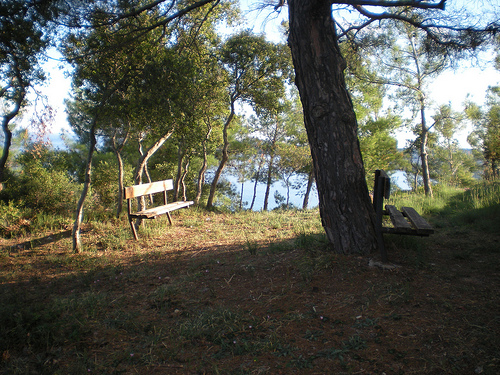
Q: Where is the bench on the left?
A: On the dirt.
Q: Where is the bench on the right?
A: On the tree.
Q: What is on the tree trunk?
A: Bark.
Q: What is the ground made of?
A: Grass and dirt.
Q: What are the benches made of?
A: Wood.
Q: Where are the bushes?
A: Behind the bench on the left.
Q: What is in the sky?
A: Clouds.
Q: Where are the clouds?
A: In the sky.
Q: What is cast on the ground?
A: Shadows.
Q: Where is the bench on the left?
A: On the ground.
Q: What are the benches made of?
A: Wood.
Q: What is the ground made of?
A: Grass and dirt.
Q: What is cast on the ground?
A: Shadows.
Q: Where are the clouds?
A: In the sky.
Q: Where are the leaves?
A: On the trees.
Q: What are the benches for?
A: Sitting.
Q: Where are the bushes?
A: Behind the left bench.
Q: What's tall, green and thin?
A: Tree trunk.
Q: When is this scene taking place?
A: Daytime.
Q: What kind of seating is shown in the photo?
A: Bench.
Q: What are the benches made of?
A: Wood.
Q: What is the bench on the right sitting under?
A: Tree.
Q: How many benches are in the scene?
A: Two.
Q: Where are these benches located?
A: Forest.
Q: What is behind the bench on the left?
A: Trees and foliage.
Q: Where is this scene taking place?
A: In a forest.